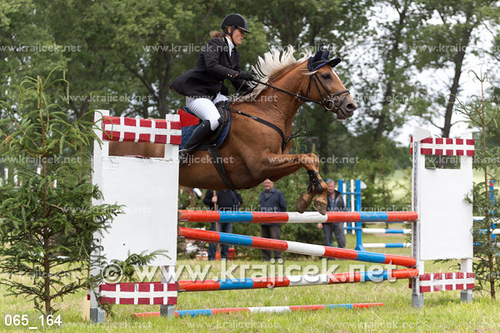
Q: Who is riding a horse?
A: A woman.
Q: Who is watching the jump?
A: People on the side.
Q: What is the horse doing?
A: Jumping.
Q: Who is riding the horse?
A: A woman.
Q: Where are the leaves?
A: On trees.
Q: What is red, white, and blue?
A: The piping.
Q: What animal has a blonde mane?
A: The horse.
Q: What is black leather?
A: The bridle.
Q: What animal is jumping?
A: The horse.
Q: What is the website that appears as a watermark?
A: Www.krajicek.net.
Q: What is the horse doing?
A: Jumping.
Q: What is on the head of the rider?
A: Helmet.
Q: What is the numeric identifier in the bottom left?
A: 065_164.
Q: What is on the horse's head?
A: A black hat.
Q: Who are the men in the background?
A: Spectators.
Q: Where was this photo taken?
A: At a horse show.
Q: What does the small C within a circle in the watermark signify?
A: Copyright.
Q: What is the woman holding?
A: Reins.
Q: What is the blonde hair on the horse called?
A: Mane.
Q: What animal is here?
A: A horse.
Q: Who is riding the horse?
A: A woman.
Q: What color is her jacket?
A: Black.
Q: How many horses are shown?
A: One.